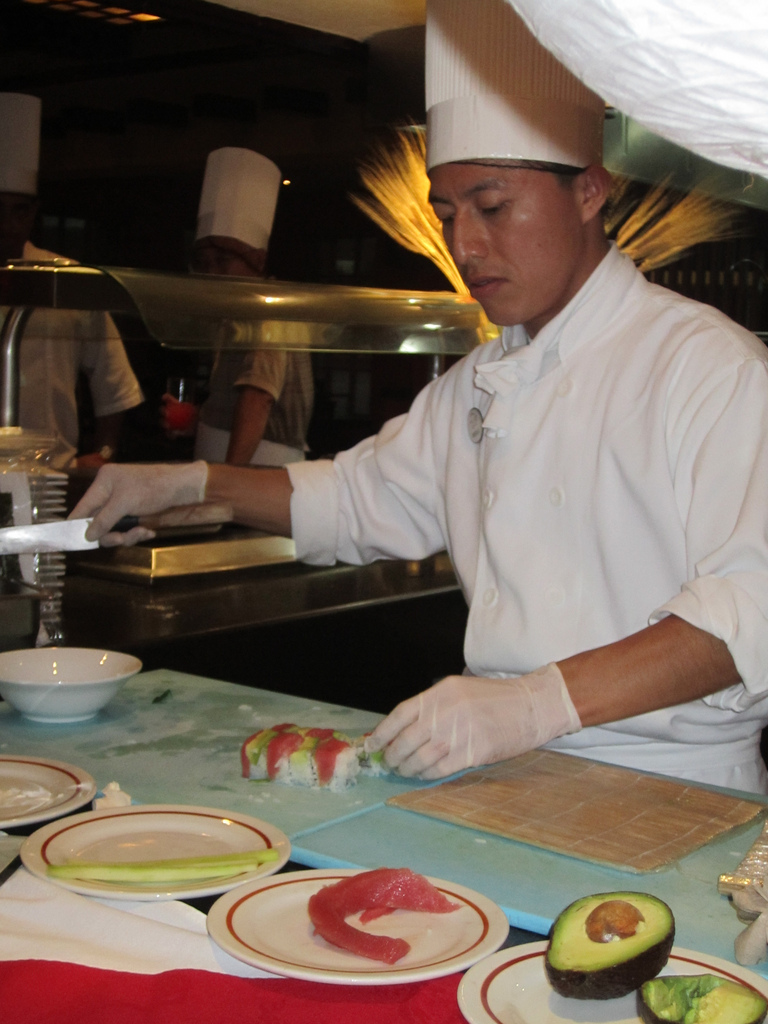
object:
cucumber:
[48, 849, 280, 881]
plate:
[20, 805, 291, 900]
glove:
[366, 662, 585, 782]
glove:
[69, 460, 211, 547]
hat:
[424, 0, 606, 172]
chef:
[69, 2, 768, 802]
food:
[310, 866, 468, 964]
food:
[638, 974, 768, 1024]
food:
[241, 723, 393, 792]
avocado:
[544, 890, 675, 1000]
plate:
[456, 937, 768, 1024]